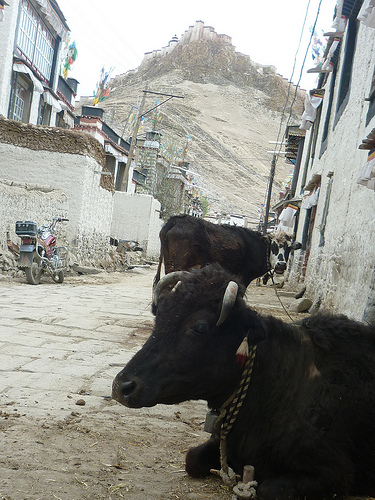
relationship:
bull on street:
[152, 214, 303, 305] [1, 266, 212, 498]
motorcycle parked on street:
[16, 214, 69, 283] [1, 262, 307, 495]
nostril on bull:
[113, 367, 140, 395] [93, 235, 371, 488]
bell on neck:
[202, 408, 223, 433] [209, 311, 291, 408]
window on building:
[9, 68, 33, 119] [2, 0, 79, 128]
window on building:
[39, 97, 50, 124] [2, 0, 79, 128]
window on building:
[14, 0, 57, 85] [2, 0, 79, 128]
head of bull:
[102, 254, 264, 413] [110, 264, 373, 497]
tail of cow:
[151, 243, 162, 290] [147, 217, 305, 318]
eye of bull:
[191, 321, 214, 336] [110, 264, 373, 497]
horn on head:
[217, 279, 236, 329] [106, 251, 250, 419]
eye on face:
[191, 321, 214, 337] [111, 277, 217, 407]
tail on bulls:
[151, 227, 162, 291] [62, 194, 374, 450]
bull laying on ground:
[152, 214, 303, 305] [0, 283, 113, 492]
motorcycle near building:
[16, 214, 69, 283] [1, 122, 113, 265]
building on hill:
[16, 23, 60, 96] [94, 19, 303, 156]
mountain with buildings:
[138, 16, 280, 102] [140, 19, 215, 62]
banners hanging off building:
[273, 187, 318, 229] [272, 0, 373, 323]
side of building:
[283, 32, 374, 332] [279, 57, 371, 243]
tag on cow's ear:
[232, 335, 262, 371] [235, 307, 266, 347]